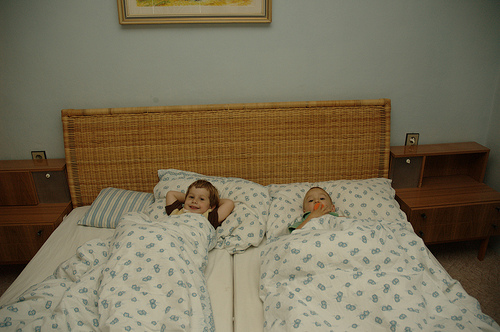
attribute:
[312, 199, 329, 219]
pacifier — orange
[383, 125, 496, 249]
table — wooden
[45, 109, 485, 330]
bed — king-size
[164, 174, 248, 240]
boy — young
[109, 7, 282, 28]
picture — framed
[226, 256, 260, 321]
mattress — white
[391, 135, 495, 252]
nightstand — wooden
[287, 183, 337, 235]
baby boy — orange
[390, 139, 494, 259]
night stand — LARGE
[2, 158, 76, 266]
night stand — LARGE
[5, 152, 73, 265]
night stand — LARGE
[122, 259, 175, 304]
designs — BLUE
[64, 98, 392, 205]
head board — STRAW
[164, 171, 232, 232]
kid — laying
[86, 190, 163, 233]
pillow — small, laying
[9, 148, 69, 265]
stand — night, standing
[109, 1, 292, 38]
picture — hanging 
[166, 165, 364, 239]
kids — laying down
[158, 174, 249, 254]
child — with hands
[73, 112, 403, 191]
headboard — wooden 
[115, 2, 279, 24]
frame — picture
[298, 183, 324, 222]
child — laying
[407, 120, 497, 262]
cupboards — Wooden 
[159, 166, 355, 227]
children — laying